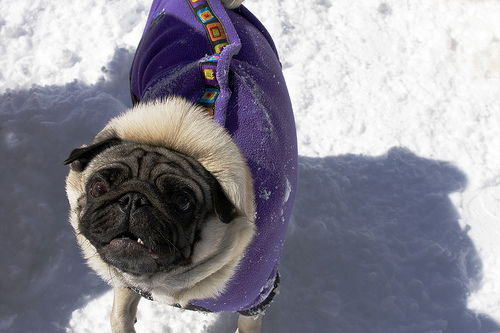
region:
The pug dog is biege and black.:
[56, 1, 308, 331]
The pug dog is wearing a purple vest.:
[123, 0, 293, 315]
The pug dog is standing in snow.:
[6, 0, 496, 331]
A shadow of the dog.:
[306, 126, 486, 331]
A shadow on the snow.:
[3, 50, 134, 330]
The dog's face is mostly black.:
[58, 136, 239, 277]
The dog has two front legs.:
[103, 281, 265, 331]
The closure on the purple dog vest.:
[186, 0, 257, 125]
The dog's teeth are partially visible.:
[128, 233, 146, 246]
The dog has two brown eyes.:
[85, 175, 196, 216]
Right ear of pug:
[59, 132, 128, 173]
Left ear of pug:
[205, 160, 247, 229]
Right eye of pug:
[79, 173, 114, 205]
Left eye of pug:
[165, 181, 196, 218]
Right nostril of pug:
[115, 192, 130, 209]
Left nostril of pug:
[132, 194, 142, 212]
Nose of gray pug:
[114, 191, 150, 217]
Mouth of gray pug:
[91, 220, 169, 266]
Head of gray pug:
[61, 134, 246, 284]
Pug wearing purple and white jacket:
[57, 1, 323, 331]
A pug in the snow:
[27, 10, 399, 332]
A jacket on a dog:
[63, 8, 332, 323]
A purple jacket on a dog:
[78, 1, 323, 331]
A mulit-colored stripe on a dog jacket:
[177, 2, 233, 132]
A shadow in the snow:
[3, 78, 82, 320]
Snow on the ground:
[298, 21, 493, 147]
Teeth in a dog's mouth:
[125, 229, 152, 250]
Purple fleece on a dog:
[232, 44, 297, 218]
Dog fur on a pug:
[119, 105, 220, 150]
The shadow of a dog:
[298, 97, 499, 328]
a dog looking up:
[51, 9, 301, 329]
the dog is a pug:
[57, 0, 307, 330]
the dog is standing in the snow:
[2, 4, 497, 330]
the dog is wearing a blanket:
[135, 0, 300, 313]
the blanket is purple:
[122, 0, 306, 306]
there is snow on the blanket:
[229, 61, 292, 239]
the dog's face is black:
[72, 141, 234, 269]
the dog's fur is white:
[64, 94, 275, 331]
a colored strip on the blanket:
[187, 2, 231, 122]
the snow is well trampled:
[5, 2, 495, 322]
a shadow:
[314, 138, 497, 330]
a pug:
[78, 159, 223, 273]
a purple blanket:
[232, 77, 301, 153]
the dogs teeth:
[131, 232, 149, 246]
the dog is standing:
[70, 3, 298, 330]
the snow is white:
[300, 0, 499, 151]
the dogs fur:
[153, 107, 203, 141]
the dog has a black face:
[88, 171, 196, 261]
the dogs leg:
[108, 300, 136, 332]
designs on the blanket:
[201, 8, 232, 77]